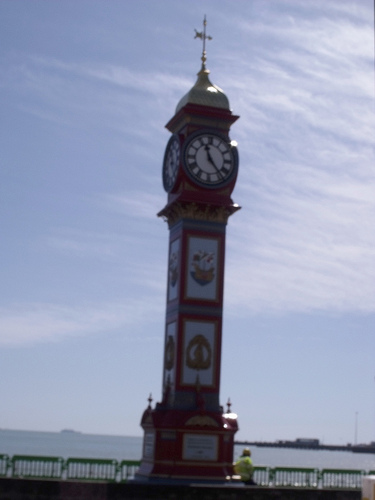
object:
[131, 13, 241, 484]
tower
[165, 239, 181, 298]
picture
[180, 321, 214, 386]
picture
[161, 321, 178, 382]
picture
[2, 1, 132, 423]
sky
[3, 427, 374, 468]
ocean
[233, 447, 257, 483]
man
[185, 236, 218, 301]
drawing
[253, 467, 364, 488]
barrier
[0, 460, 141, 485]
barrier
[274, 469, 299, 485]
bar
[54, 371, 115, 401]
water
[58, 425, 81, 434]
ship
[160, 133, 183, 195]
clock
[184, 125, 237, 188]
clock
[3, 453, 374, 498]
pier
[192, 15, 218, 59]
vane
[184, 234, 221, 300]
clock pillar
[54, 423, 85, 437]
silhouette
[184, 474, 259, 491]
reflection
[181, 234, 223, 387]
decorations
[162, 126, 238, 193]
clock